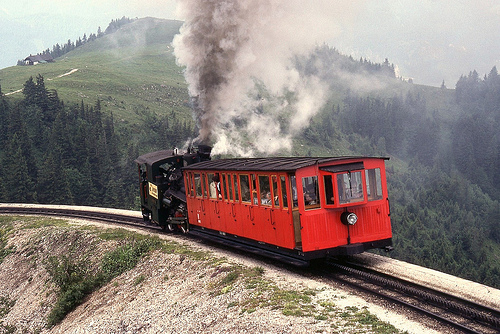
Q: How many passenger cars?
A: One.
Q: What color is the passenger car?
A: Red.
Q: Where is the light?
A: Front of passenger car.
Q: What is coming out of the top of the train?
A: Smoke.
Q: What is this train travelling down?
A: Tracks.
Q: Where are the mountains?
A: Surrounding train.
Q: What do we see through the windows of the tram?
A: People.